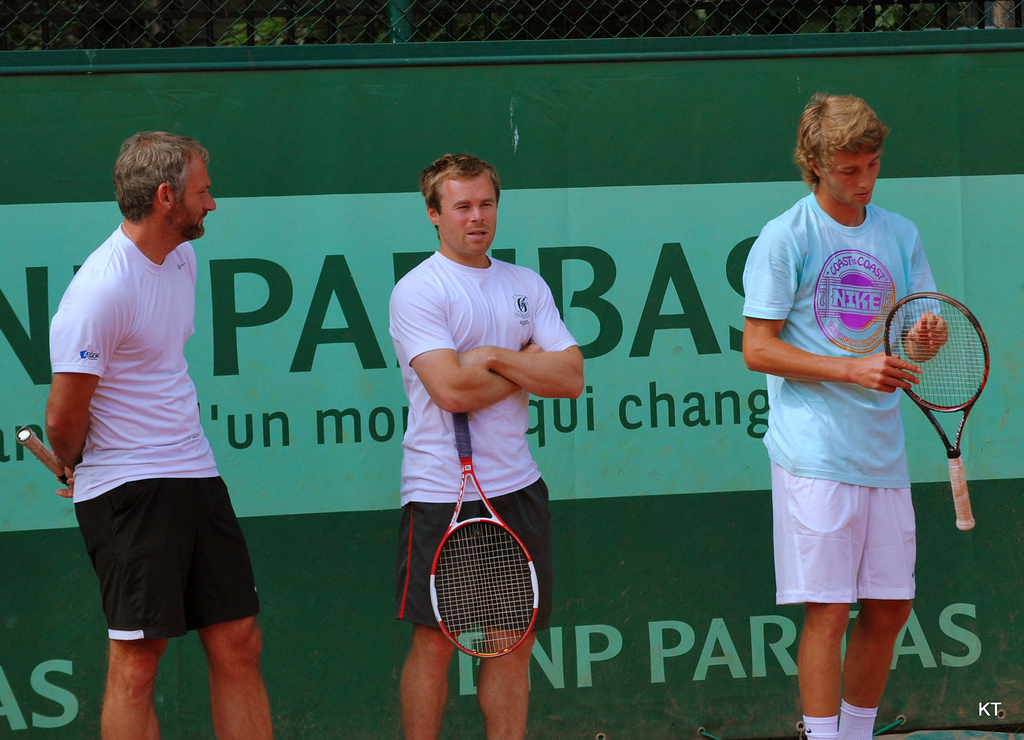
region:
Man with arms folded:
[342, 117, 662, 437]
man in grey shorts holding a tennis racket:
[377, 134, 622, 732]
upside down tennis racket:
[422, 397, 552, 669]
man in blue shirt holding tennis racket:
[737, 83, 987, 733]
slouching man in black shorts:
[39, 122, 311, 729]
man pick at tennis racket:
[735, 77, 991, 725]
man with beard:
[100, 121, 225, 252]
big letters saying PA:
[203, 247, 391, 390]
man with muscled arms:
[371, 133, 603, 424]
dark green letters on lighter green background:
[203, 242, 390, 376]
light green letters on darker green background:
[634, 602, 749, 695]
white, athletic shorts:
[756, 450, 941, 618]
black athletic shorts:
[65, 466, 285, 643]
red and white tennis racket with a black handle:
[421, 412, 548, 663]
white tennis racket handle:
[5, 424, 82, 483]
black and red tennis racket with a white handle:
[866, 283, 1022, 539]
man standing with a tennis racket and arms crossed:
[380, 140, 603, 735]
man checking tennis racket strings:
[724, 84, 1003, 736]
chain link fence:
[5, 1, 1021, 33]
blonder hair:
[810, 103, 872, 141]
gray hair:
[128, 141, 179, 174]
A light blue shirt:
[739, 195, 976, 485]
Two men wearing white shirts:
[35, 135, 620, 575]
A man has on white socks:
[776, 683, 924, 733]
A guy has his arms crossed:
[370, 125, 672, 509]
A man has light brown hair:
[749, 64, 916, 247]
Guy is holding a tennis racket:
[351, 137, 612, 665]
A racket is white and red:
[366, 386, 598, 686]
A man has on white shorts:
[717, 423, 962, 645]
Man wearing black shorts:
[13, 394, 309, 672]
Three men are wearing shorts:
[27, 367, 969, 694]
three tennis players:
[24, 92, 1012, 728]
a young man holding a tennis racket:
[379, 140, 604, 717]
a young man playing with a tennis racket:
[720, 82, 992, 703]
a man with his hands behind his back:
[9, 74, 269, 735]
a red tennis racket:
[420, 392, 553, 677]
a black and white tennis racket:
[872, 285, 994, 583]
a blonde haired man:
[760, 68, 928, 240]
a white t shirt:
[39, 225, 283, 504]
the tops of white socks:
[793, 680, 892, 737]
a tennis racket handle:
[937, 456, 999, 543]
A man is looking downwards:
[764, 90, 914, 255]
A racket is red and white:
[421, 382, 563, 694]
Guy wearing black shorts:
[50, 441, 315, 663]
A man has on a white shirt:
[349, 150, 596, 543]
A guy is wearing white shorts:
[731, 64, 961, 668]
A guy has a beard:
[113, 111, 269, 309]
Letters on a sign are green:
[187, 191, 813, 430]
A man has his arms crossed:
[355, 129, 610, 452]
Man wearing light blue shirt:
[684, 146, 976, 520]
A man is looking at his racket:
[749, 93, 988, 565]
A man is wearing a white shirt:
[33, 106, 263, 546]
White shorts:
[743, 403, 980, 654]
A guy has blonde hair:
[774, 71, 885, 242]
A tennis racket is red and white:
[390, 403, 577, 685]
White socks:
[766, 680, 900, 736]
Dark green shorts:
[39, 446, 282, 691]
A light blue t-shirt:
[729, 163, 949, 523]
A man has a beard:
[82, 108, 245, 254]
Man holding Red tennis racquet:
[376, 99, 558, 730]